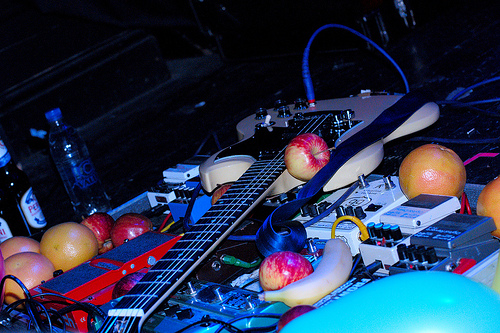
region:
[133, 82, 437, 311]
a white guitar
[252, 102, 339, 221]
a apple sitting on a guitar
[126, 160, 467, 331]
sound equipment with fruit laying on it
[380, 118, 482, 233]
a orange on a table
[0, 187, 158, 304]
several apples and oranges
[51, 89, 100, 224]
a clear water bottle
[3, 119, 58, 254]
a brown beer bottle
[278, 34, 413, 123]
a blue cord connected to a guitar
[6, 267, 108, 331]
several cords and cables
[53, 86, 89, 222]
a plastic water bottle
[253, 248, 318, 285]
a red and yellow apple on a sound board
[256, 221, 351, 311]
a banana on a sound board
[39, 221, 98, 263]
an orange on a sound board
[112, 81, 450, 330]
a plugged in electric guitar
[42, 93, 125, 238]
a water bottle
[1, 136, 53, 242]
a bottle of beer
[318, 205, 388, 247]
a yellow cord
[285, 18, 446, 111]
a blue cord attached to an electric guitar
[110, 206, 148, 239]
a solid red apple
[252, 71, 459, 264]
a blue strap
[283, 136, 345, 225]
apple is red and yellow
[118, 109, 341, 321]
apple is on guitar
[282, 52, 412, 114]
guitar is plugged in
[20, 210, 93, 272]
fruit near bottle of water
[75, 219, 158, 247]
apples near bottle of water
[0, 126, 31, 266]
beer bottles near water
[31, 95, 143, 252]
water bottle is clear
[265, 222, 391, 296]
banana near apple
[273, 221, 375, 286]
banana near guitar amp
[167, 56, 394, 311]
guitar is two-tone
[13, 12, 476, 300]
a sound system and guitar with fruit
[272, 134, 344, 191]
a red apple with a long stem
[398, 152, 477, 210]
a large grapefruit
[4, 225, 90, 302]
3 large citrus fruits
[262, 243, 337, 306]
an apple and a banana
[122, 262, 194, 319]
frets on a guitar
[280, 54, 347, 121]
a cord plugged in to an electric guitar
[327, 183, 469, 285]
some sound peddles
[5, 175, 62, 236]
a bottle of perroni beer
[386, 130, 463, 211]
one orange on table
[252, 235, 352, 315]
a banana and apple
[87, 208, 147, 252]
two red apples on table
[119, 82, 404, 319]
a guitar on table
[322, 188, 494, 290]
gray and black amp pedals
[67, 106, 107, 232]
a bottle of water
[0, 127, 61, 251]
two bottles of beer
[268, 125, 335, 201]
a yellow and red apple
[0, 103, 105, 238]
drinks on a table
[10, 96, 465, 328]
a guitar and fruit